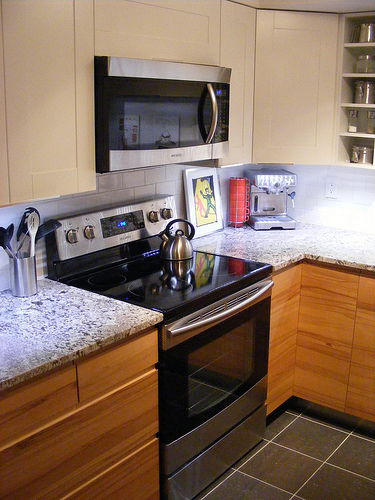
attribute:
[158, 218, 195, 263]
kettle — metal, silver, black, for coffee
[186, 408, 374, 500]
linoleum — black, tiled, clean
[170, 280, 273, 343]
handle — silver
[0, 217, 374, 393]
countertop — marble, granite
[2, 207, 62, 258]
utensils — black, white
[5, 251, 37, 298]
pot — round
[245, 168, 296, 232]
machine — silver, for esspresso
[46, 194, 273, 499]
stove — steel, black, silver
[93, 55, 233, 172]
microwave — black, silver, metallic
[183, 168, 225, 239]
picture — colorful, framed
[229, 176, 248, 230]
cups — orange, red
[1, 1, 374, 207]
cabinets — on top, wooden, brown, white